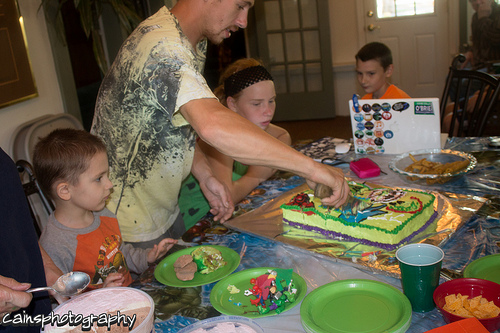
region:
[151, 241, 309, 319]
two green plastic plates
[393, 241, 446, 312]
green plastic beverage cup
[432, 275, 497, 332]
bowl holding chips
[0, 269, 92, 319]
fingers holding a spoon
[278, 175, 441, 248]
green frosted layer cake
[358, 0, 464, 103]
front door with glass windows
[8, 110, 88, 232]
two fold-up chairs stacked against wall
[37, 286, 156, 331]
container of neapolitan ice cream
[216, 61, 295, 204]
child wearing a black head band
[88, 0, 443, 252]
man cutting a cake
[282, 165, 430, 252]
a green cake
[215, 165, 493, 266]
tinfoil under a birthday cake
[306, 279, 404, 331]
a stack of green plates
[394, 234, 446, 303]
a green plastic cup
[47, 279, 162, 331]
a tub of ice cream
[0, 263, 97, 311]
a spoon in a hand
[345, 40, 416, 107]
a boy in an orange shirt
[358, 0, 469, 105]
a white door of a house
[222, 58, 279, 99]
a black headband on a girl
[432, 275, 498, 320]
a red bowl with chips inside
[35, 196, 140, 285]
little boy's shirt is orange and gray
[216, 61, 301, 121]
girl wearing a black headband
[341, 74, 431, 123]
boy wearing orange shirt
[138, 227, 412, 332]
the plates are green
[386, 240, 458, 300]
the cup is green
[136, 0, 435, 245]
man is cutting cake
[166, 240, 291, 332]
cake is on the plate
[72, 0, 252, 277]
man's shirt is white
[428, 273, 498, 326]
red bowl next to plate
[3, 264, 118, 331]
person holding a spoon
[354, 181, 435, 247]
Yellow birthday cake with colorful decorations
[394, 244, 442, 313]
Green plastic cup on table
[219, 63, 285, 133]
Girl wearing a black headband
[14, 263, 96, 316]
Spoon being held in a hand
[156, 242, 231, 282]
Green plate with cake and ice cream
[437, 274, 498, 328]
Red bowl of chips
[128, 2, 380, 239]
Man slicing the birthday cake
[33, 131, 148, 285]
Young boy watching the cake being cut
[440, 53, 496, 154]
Black wooden chair back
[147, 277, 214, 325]
Incredible Hunk on table cloth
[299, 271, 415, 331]
The plates are green.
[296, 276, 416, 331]
A stack of paper plates.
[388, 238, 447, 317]
The cup is green.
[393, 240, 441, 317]
The cup is plastic.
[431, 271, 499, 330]
The bowl is red.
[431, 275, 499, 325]
There are chips in the bowl.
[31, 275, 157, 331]
A container of ice cream.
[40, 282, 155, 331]
The ice cream is neopolitan.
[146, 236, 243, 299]
Cake and ice cream on a plate.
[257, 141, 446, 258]
The cake is being cut.